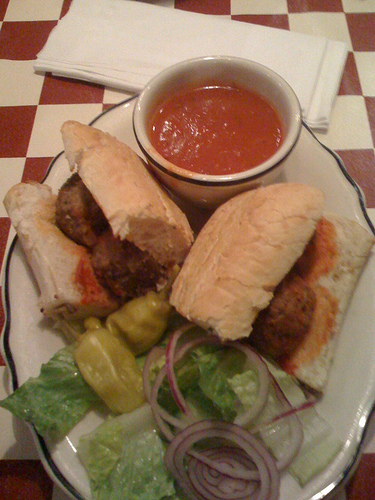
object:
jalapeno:
[85, 320, 133, 397]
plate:
[41, 129, 348, 491]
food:
[6, 49, 323, 482]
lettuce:
[0, 333, 346, 499]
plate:
[307, 158, 369, 218]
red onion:
[162, 342, 213, 405]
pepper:
[104, 277, 172, 356]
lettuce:
[1, 345, 105, 452]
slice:
[165, 319, 194, 413]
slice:
[142, 345, 269, 429]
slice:
[163, 420, 280, 498]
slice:
[176, 428, 269, 497]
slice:
[188, 448, 260, 496]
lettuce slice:
[2, 334, 130, 435]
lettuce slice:
[81, 333, 345, 499]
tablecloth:
[30, 71, 54, 164]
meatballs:
[54, 173, 163, 293]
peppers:
[79, 281, 174, 412]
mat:
[5, 40, 77, 174]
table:
[2, 3, 370, 495]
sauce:
[70, 255, 109, 311]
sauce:
[307, 221, 343, 286]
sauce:
[284, 288, 338, 378]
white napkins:
[59, 9, 204, 60]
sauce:
[321, 252, 334, 278]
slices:
[141, 325, 315, 498]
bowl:
[129, 48, 313, 209]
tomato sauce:
[145, 79, 285, 182]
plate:
[2, 84, 373, 497]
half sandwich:
[2, 125, 197, 313]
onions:
[153, 416, 298, 498]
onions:
[148, 321, 283, 429]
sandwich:
[2, 166, 373, 392]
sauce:
[167, 73, 271, 155]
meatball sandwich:
[2, 114, 371, 402]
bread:
[179, 181, 360, 388]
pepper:
[50, 317, 146, 412]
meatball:
[264, 249, 321, 358]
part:
[227, 52, 263, 85]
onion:
[158, 330, 295, 493]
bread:
[166, 180, 373, 396]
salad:
[1, 287, 343, 498]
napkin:
[31, 0, 346, 132]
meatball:
[50, 169, 108, 250]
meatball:
[91, 227, 163, 310]